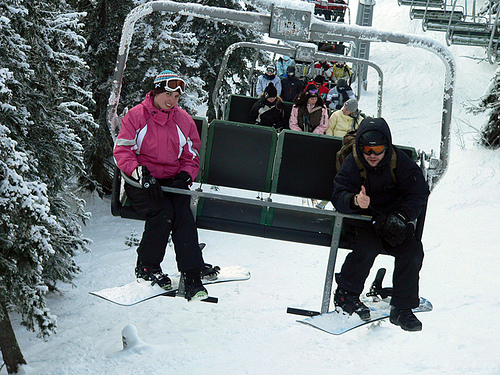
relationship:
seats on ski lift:
[135, 93, 450, 275] [86, 0, 457, 339]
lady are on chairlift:
[110, 67, 223, 300] [106, 0, 458, 318]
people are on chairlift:
[329, 116, 423, 331] [106, 0, 458, 318]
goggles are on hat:
[156, 76, 187, 98] [155, 67, 177, 82]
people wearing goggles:
[329, 116, 423, 331] [359, 144, 394, 155]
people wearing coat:
[329, 116, 423, 331] [326, 159, 474, 262]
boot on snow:
[389, 307, 424, 332] [2, 0, 499, 372]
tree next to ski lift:
[0, 0, 100, 373] [106, 0, 456, 315]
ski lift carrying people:
[107, 0, 457, 264] [329, 116, 423, 331]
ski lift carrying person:
[107, 0, 457, 264] [114, 70, 219, 321]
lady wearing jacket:
[323, 95, 367, 148] [322, 110, 364, 138]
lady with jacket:
[330, 95, 355, 137] [322, 110, 347, 137]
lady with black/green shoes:
[110, 67, 223, 305] [181, 273, 208, 305]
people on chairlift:
[329, 116, 423, 331] [138, 31, 485, 226]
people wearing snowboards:
[108, 70, 423, 337] [93, 258, 433, 332]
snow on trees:
[8, 162, 45, 214] [5, 5, 112, 182]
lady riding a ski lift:
[110, 67, 223, 300] [86, 0, 471, 332]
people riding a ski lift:
[329, 116, 423, 331] [86, 0, 471, 332]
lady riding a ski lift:
[323, 95, 367, 148] [86, 0, 471, 332]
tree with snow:
[0, 0, 100, 373] [22, 178, 49, 219]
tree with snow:
[66, 2, 213, 197] [22, 178, 49, 219]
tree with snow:
[188, 2, 275, 121] [22, 178, 49, 219]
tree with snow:
[466, 64, 499, 150] [22, 178, 49, 219]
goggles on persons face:
[359, 144, 386, 156] [362, 145, 388, 167]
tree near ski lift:
[0, 0, 100, 373] [106, 0, 456, 315]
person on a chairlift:
[256, 64, 283, 96] [244, 46, 364, 106]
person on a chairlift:
[280, 67, 302, 99] [244, 46, 364, 106]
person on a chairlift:
[306, 75, 327, 97] [244, 46, 364, 106]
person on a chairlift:
[326, 77, 351, 106] [244, 46, 364, 106]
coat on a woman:
[112, 92, 205, 188] [259, 57, 284, 98]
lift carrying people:
[75, 0, 489, 345] [119, 39, 429, 340]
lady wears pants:
[110, 67, 223, 300] [127, 176, 207, 275]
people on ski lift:
[329, 116, 423, 331] [86, 0, 457, 339]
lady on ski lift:
[110, 67, 223, 300] [86, 0, 457, 339]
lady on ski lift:
[323, 95, 367, 148] [86, 0, 457, 339]